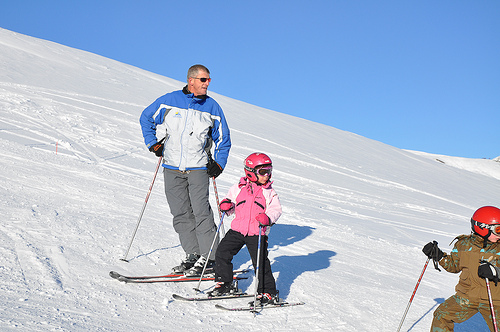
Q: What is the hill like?
A: Slopey.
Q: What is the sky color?
A: Blue.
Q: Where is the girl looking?
A: Downward.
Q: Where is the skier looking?
A: Downward.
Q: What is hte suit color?
A: Brown.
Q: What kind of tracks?
A: Ski tracks.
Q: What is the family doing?
A: Skiing.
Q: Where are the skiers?
A: On a hill.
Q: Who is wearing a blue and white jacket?
A: The man.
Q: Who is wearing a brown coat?
A: The young boy.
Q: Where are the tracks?
A: In the snow.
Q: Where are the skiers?
A: In the snow.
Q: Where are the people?
A: On a snowy hill.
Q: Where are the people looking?
A: To the side.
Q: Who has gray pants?
A: The adult.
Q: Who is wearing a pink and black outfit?
A: The child.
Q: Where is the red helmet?
A: On the child.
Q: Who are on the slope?
A: The family.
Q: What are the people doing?
A: Skiing.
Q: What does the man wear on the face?
A: Sunglasses.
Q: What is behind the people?
A: Shadows.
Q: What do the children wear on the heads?
A: Helmets.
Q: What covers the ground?
A: Snow.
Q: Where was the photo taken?
A: Mountain.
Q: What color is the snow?
A: White.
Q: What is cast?
A: Shadow.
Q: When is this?
A: Daytime.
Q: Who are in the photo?
A: People.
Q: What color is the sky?
A: Blue.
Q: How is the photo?
A: Clear.